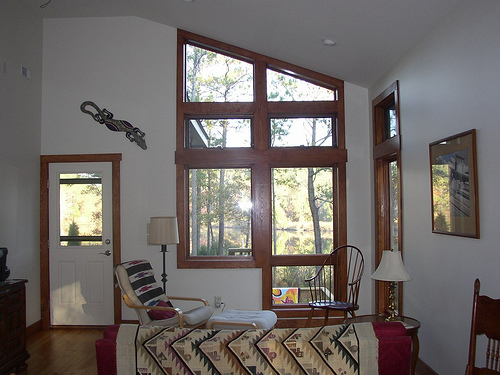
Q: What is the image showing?
A: It is showing a living room.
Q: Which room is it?
A: It is a living room.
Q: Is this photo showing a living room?
A: Yes, it is showing a living room.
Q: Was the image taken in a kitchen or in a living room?
A: It was taken at a living room.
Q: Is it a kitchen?
A: No, it is a living room.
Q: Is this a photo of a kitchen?
A: No, the picture is showing a living room.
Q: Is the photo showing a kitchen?
A: No, the picture is showing a living room.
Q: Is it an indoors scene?
A: Yes, it is indoors.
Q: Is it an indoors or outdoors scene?
A: It is indoors.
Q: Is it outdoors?
A: No, it is indoors.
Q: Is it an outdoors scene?
A: No, it is indoors.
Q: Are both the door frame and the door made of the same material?
A: Yes, both the door frame and the door are made of wood.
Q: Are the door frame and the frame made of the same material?
A: Yes, both the door frame and the frame are made of wood.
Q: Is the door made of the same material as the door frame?
A: Yes, both the door and the door frame are made of wood.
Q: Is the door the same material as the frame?
A: Yes, both the door and the frame are made of wood.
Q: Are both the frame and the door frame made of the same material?
A: Yes, both the frame and the door frame are made of wood.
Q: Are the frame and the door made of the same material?
A: Yes, both the frame and the door are made of wood.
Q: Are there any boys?
A: No, there are no boys.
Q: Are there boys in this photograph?
A: No, there are no boys.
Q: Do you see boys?
A: No, there are no boys.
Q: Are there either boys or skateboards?
A: No, there are no boys or skateboards.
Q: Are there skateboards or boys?
A: No, there are no boys or skateboards.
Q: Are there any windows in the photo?
A: Yes, there is a window.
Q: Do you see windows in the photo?
A: Yes, there is a window.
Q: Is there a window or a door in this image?
A: Yes, there is a window.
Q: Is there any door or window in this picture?
A: Yes, there is a window.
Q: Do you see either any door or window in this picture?
A: Yes, there is a window.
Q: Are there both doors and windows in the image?
A: Yes, there are both a window and a door.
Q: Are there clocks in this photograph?
A: No, there are no clocks.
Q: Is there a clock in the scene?
A: No, there are no clocks.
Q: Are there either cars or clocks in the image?
A: No, there are no clocks or cars.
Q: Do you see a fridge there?
A: No, there are no refrigerators.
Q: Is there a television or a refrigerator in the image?
A: No, there are no refrigerators or televisions.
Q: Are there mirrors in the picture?
A: No, there are no mirrors.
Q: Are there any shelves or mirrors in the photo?
A: No, there are no mirrors or shelves.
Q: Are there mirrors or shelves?
A: No, there are no mirrors or shelves.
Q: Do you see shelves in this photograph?
A: No, there are no shelves.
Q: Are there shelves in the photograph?
A: No, there are no shelves.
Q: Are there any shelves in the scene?
A: No, there are no shelves.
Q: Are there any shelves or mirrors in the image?
A: No, there are no shelves or mirrors.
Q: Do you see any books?
A: No, there are no books.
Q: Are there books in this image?
A: No, there are no books.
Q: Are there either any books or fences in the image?
A: No, there are no books or fences.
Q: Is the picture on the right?
A: Yes, the picture is on the right of the image.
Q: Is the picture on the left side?
A: No, the picture is on the right of the image.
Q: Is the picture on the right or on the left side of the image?
A: The picture is on the right of the image.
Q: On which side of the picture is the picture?
A: The picture is on the right of the image.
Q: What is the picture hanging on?
A: The picture is hanging on the wall.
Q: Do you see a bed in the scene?
A: No, there are no beds.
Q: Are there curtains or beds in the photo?
A: No, there are no beds or curtains.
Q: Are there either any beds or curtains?
A: No, there are no beds or curtains.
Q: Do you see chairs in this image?
A: Yes, there is a chair.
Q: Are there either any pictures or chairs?
A: Yes, there is a chair.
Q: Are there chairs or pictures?
A: Yes, there is a chair.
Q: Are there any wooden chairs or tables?
A: Yes, there is a wood chair.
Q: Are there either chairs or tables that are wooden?
A: Yes, the chair is wooden.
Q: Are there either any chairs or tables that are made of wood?
A: Yes, the chair is made of wood.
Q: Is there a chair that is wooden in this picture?
A: Yes, there is a wood chair.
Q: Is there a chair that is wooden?
A: Yes, there is a chair that is wooden.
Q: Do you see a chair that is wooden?
A: Yes, there is a chair that is wooden.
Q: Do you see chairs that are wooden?
A: Yes, there is a chair that is wooden.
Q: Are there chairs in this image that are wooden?
A: Yes, there is a chair that is wooden.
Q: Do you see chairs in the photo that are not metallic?
A: Yes, there is a wooden chair.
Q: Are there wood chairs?
A: Yes, there is a chair that is made of wood.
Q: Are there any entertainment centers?
A: No, there are no entertainment centers.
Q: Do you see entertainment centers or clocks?
A: No, there are no entertainment centers or clocks.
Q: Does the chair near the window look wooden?
A: Yes, the chair is wooden.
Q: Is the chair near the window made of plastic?
A: No, the chair is made of wood.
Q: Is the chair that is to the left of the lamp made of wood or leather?
A: The chair is made of wood.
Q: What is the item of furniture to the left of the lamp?
A: The piece of furniture is a chair.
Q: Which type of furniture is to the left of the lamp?
A: The piece of furniture is a chair.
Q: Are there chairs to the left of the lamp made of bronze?
A: Yes, there is a chair to the left of the lamp.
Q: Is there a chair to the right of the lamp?
A: No, the chair is to the left of the lamp.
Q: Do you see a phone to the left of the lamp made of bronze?
A: No, there is a chair to the left of the lamp.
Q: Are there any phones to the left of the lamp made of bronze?
A: No, there is a chair to the left of the lamp.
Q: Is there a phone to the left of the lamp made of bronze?
A: No, there is a chair to the left of the lamp.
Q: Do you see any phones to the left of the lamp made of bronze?
A: No, there is a chair to the left of the lamp.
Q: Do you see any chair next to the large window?
A: Yes, there is a chair next to the window.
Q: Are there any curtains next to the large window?
A: No, there is a chair next to the window.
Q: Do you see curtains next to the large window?
A: No, there is a chair next to the window.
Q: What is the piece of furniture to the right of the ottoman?
A: The piece of furniture is a chair.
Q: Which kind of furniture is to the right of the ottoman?
A: The piece of furniture is a chair.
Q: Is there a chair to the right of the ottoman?
A: Yes, there is a chair to the right of the ottoman.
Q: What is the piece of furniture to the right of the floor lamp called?
A: The piece of furniture is a chair.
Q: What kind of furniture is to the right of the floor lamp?
A: The piece of furniture is a chair.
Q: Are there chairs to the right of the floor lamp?
A: Yes, there is a chair to the right of the floor lamp.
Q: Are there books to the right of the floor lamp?
A: No, there is a chair to the right of the floor lamp.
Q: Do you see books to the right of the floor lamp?
A: No, there is a chair to the right of the floor lamp.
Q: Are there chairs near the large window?
A: Yes, there is a chair near the window.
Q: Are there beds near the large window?
A: No, there is a chair near the window.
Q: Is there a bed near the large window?
A: No, there is a chair near the window.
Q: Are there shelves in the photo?
A: No, there are no shelves.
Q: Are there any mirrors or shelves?
A: No, there are no shelves or mirrors.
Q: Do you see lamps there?
A: Yes, there is a lamp.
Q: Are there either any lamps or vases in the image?
A: Yes, there is a lamp.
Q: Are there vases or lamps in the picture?
A: Yes, there is a lamp.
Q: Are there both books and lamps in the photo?
A: No, there is a lamp but no books.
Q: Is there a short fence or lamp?
A: Yes, there is a short lamp.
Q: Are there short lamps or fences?
A: Yes, there is a short lamp.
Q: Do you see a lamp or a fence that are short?
A: Yes, the lamp is short.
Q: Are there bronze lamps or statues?
A: Yes, there is a bronze lamp.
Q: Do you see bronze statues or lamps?
A: Yes, there is a bronze lamp.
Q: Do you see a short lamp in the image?
A: Yes, there is a short lamp.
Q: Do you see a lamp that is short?
A: Yes, there is a lamp that is short.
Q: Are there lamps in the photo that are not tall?
A: Yes, there is a short lamp.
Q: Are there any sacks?
A: No, there are no sacks.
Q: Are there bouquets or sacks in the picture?
A: No, there are no sacks or bouquets.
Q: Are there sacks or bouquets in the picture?
A: No, there are no sacks or bouquets.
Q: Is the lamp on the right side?
A: Yes, the lamp is on the right of the image.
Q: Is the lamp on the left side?
A: No, the lamp is on the right of the image.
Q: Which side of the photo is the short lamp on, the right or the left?
A: The lamp is on the right of the image.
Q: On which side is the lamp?
A: The lamp is on the right of the image.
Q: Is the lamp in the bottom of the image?
A: Yes, the lamp is in the bottom of the image.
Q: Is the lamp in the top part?
A: No, the lamp is in the bottom of the image.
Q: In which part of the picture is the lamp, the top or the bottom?
A: The lamp is in the bottom of the image.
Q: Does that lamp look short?
A: Yes, the lamp is short.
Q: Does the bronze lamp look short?
A: Yes, the lamp is short.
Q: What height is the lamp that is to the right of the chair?
A: The lamp is short.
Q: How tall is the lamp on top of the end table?
A: The lamp is short.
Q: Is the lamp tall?
A: No, the lamp is short.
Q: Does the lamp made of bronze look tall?
A: No, the lamp is short.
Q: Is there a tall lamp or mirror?
A: No, there is a lamp but it is short.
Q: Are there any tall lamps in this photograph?
A: No, there is a lamp but it is short.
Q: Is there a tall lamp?
A: No, there is a lamp but it is short.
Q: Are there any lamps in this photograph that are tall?
A: No, there is a lamp but it is short.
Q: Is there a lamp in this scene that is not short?
A: No, there is a lamp but it is short.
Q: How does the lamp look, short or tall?
A: The lamp is short.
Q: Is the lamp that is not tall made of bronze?
A: Yes, the lamp is made of bronze.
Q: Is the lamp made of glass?
A: No, the lamp is made of bronze.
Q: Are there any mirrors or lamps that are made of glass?
A: No, there is a lamp but it is made of bronze.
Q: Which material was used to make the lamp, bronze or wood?
A: The lamp is made of bronze.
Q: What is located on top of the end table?
A: The lamp is on top of the end table.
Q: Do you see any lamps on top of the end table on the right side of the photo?
A: Yes, there is a lamp on top of the end table.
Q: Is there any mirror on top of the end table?
A: No, there is a lamp on top of the end table.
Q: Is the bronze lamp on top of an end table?
A: Yes, the lamp is on top of an end table.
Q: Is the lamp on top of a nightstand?
A: No, the lamp is on top of an end table.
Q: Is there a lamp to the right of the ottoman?
A: Yes, there is a lamp to the right of the ottoman.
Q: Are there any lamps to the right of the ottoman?
A: Yes, there is a lamp to the right of the ottoman.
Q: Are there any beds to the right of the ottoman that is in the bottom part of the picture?
A: No, there is a lamp to the right of the ottoman.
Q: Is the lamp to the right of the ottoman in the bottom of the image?
A: Yes, the lamp is to the right of the ottoman.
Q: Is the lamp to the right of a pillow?
A: No, the lamp is to the right of the ottoman.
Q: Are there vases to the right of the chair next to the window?
A: No, there is a lamp to the right of the chair.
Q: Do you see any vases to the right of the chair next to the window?
A: No, there is a lamp to the right of the chair.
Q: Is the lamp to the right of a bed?
A: No, the lamp is to the right of the chair.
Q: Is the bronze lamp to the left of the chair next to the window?
A: No, the lamp is to the right of the chair.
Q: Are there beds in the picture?
A: No, there are no beds.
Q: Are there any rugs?
A: No, there are no rugs.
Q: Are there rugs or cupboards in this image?
A: No, there are no rugs or cupboards.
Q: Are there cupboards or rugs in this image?
A: No, there are no rugs or cupboards.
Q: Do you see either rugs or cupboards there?
A: No, there are no rugs or cupboards.